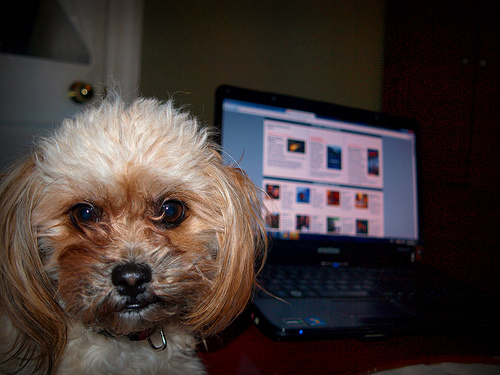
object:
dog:
[0, 92, 276, 374]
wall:
[141, 0, 385, 130]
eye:
[159, 196, 187, 227]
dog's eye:
[66, 196, 104, 229]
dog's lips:
[113, 299, 161, 311]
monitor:
[211, 84, 424, 269]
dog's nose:
[105, 259, 157, 295]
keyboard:
[252, 257, 421, 300]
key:
[287, 289, 304, 299]